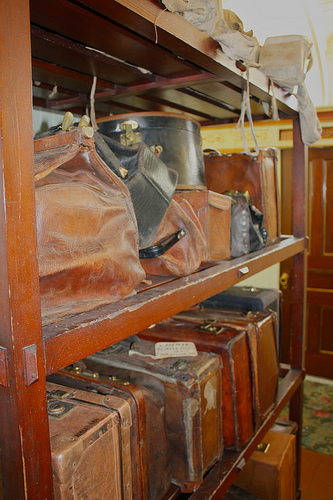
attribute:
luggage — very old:
[29, 100, 283, 306]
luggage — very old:
[50, 279, 292, 492]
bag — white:
[254, 31, 311, 88]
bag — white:
[163, 1, 266, 63]